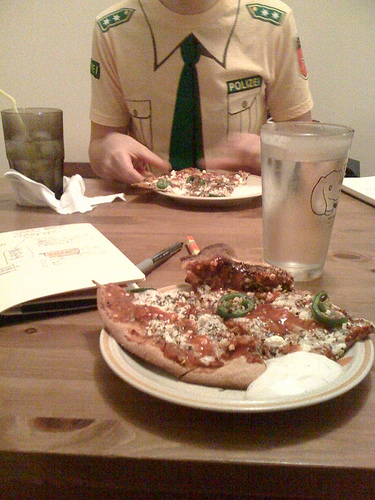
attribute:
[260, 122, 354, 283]
glass — clear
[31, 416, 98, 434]
knot — brown, small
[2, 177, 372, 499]
table — wooden, unpolished, thick, brown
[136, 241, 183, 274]
pen — grey, black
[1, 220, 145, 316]
notebook — small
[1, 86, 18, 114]
straw — yellow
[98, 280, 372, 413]
plate — white, clean, gold\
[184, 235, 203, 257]
pen — orange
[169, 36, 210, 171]
tie — green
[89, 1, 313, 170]
shirt — tan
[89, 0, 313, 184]
man — light skinned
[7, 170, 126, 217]
napkin — white, folded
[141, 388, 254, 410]
trim — gold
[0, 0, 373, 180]
wall — white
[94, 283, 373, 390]
pizza — large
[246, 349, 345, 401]
sauce — white